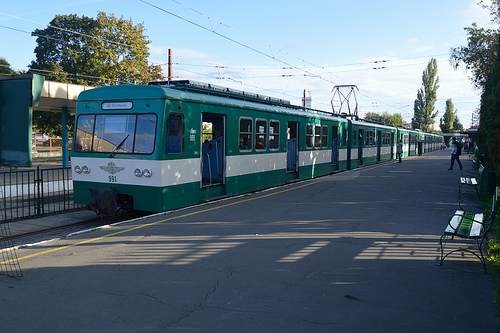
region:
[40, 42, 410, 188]
A green and white train on the tracks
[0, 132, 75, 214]
A black gate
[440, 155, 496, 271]
Benches outside of the train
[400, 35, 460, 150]
Cypress trees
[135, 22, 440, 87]
Telephone wires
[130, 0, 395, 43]
Clear blue sky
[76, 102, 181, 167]
The front of the train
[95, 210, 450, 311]
The train platfrom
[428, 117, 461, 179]
People walking on the train platform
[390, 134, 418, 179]
Person about to get on the train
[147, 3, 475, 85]
The sky is clear blue.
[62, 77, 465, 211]
The train is green.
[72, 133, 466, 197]
The train has a white strip.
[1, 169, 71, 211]
The fence is metal.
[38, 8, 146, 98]
The tree is leafy.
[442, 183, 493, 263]
The bench is empty.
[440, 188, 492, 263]
The bench is white and green.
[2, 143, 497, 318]
The side walk is concrete.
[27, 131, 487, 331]
The sidewalk is empty.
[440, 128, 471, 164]
The person is walking.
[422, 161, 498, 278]
a white and green bench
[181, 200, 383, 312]
shadows on the ground of the sidewalk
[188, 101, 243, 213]
an open train door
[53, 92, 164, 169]
a train windshield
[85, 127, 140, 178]
windshield wipers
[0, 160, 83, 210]
black metal gate around the train tracks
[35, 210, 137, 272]
yellow stripe on the ground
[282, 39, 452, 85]
cables in the sky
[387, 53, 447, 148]
tall green tree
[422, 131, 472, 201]
a person walking toward the train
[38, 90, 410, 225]
A green and white train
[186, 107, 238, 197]
The door to the train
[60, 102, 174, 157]
Window of a door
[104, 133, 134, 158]
A windshield wiper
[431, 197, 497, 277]
A bench on concert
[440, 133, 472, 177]
A man walking toward the train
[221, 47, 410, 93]
Wires for the train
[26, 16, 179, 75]
Large green tree in behind the train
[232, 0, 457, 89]
Clouds in the sky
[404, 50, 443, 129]
A tall green tree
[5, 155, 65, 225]
A black metal railing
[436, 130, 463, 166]
A person walking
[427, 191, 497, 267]
A brown bench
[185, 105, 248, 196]
Door to the train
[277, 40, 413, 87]
Electric lines for the train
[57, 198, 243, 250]
Yellow strip along the rail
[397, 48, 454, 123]
A tall green tree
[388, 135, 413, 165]
a person waiting to get on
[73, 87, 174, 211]
the front end of the train